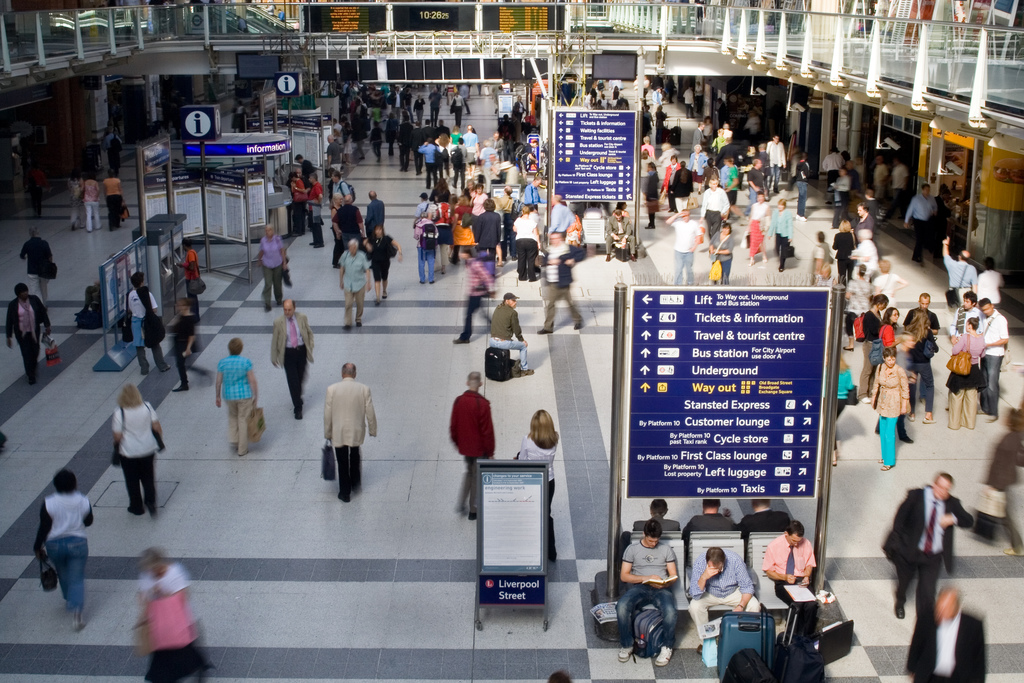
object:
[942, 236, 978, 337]
man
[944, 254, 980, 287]
shirt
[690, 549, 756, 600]
shirt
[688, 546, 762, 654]
man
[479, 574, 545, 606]
blue sign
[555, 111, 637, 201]
sign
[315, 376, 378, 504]
suit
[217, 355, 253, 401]
shirt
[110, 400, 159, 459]
shirt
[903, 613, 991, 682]
suit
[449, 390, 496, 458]
coat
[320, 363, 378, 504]
man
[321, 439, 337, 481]
bag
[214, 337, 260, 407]
top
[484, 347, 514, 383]
bag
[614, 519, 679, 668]
man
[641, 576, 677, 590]
book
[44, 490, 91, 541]
shirt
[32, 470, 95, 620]
woman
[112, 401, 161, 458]
blouse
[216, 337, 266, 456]
lady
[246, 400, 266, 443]
bag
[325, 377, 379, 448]
coat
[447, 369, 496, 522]
man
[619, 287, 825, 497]
sign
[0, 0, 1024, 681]
station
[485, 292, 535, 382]
man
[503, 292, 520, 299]
hat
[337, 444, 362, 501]
pant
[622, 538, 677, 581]
shirt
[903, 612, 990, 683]
jacket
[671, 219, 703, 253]
shirt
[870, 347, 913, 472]
woman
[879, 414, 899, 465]
pants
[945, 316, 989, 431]
woman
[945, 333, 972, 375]
purse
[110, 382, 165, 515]
woman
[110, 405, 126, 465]
purse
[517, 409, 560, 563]
person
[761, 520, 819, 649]
person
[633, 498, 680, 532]
person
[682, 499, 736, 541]
person